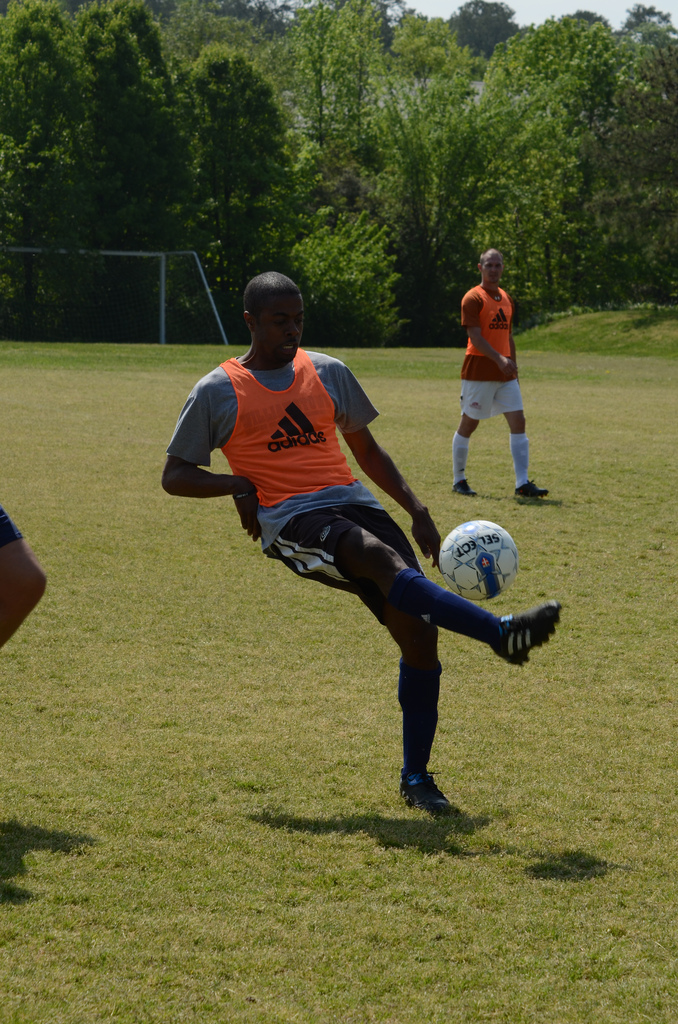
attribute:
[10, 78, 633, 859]
picture —  outdoors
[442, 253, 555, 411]
vest — bright orange 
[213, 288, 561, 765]
man — orange 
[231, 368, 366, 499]
vest — Bright orange Adidas 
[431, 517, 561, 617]
ball — Soccer  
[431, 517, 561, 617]
stripe — blue 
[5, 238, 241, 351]
goal — Soccer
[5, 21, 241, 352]
tree — under  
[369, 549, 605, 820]
shoes — Black soccer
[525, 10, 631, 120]
green tree — Lush green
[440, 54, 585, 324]
green tree — soccer 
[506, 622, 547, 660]
stripes — white 